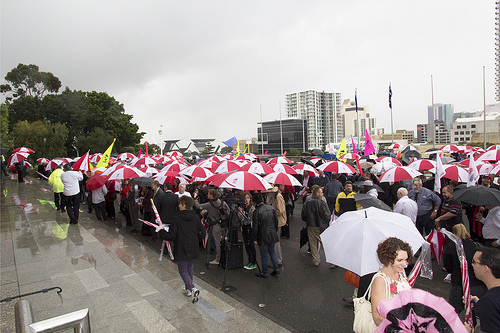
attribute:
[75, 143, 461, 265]
crowd — people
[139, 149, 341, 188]
umbrellas — white, red, identical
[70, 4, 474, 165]
weather — rainy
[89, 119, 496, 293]
people — standing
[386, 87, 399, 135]
pole — tall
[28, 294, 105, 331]
stairs — wet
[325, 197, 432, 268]
umbrella — white, solid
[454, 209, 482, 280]
umbrellas — closed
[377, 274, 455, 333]
umbrella — pink, black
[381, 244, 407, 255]
hair — brown, curly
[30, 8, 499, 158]
sky — gray, white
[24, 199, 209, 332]
ground — wet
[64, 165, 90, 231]
man — walking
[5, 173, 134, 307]
sidewalk — wet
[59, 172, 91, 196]
shirt — white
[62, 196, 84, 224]
pants — black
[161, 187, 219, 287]
woman — walking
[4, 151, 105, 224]
people — walking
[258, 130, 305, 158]
building — glass, tall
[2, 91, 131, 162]
trees — green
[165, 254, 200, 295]
pants — purple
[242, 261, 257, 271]
shoes — green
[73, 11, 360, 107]
clouds — rain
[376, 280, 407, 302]
top — tank, white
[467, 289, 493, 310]
shirt — black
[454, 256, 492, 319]
umbrella — not open, red, white